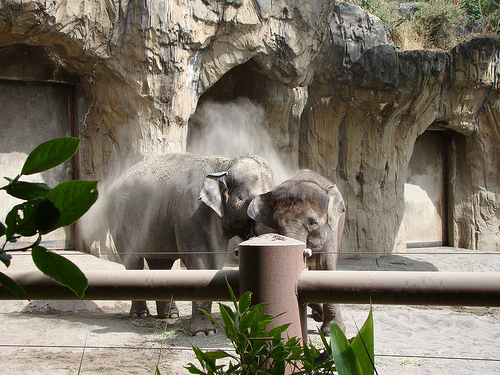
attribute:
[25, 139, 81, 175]
leaf — green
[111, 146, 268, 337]
elephant — behind, enclosed, standing, single, grey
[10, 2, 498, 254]
wall — backward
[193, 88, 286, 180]
water — flowing, falling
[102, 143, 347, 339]
elephants — standing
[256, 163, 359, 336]
elephant — enlosed, standing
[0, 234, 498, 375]
fence — metallic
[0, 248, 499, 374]
floor — sandy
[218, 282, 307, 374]
tree — green